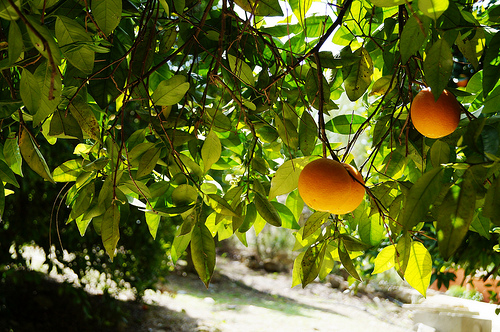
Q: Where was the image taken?
A: It was taken at the road.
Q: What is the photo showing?
A: It is showing a road.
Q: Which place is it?
A: It is a road.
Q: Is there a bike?
A: No, there are no bikes.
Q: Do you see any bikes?
A: No, there are no bikes.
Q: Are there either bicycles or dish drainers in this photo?
A: No, there are no bicycles or dish drainers.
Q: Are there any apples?
A: No, there are no apples.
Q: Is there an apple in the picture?
A: No, there are no apples.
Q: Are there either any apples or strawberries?
A: No, there are no apples or strawberries.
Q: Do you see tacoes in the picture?
A: No, there are no tacoes.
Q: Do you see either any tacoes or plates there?
A: No, there are no tacoes or plates.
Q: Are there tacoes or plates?
A: No, there are no tacoes or plates.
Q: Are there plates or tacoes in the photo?
A: No, there are no tacoes or plates.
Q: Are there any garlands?
A: No, there are no garlands.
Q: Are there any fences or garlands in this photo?
A: No, there are no garlands or fences.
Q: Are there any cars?
A: No, there are no cars.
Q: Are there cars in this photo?
A: No, there are no cars.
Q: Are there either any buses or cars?
A: No, there are no cars or buses.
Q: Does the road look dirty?
A: Yes, the road is dirty.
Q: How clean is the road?
A: The road is dirty.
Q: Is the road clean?
A: No, the road is dirty.